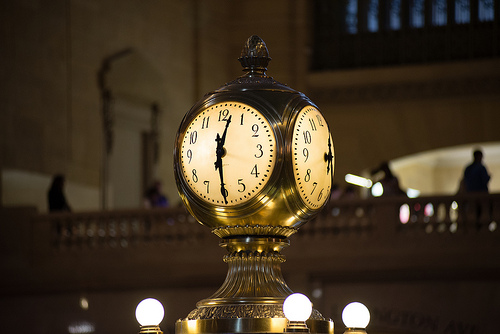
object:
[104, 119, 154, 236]
door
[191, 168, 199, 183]
numbers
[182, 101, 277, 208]
clock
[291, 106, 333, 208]
clock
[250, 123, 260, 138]
number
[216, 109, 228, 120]
number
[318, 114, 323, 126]
number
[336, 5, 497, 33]
windows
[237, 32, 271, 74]
brass piece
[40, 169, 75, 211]
person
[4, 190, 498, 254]
fence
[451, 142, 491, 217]
person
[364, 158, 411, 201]
person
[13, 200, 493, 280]
balcony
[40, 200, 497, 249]
barrier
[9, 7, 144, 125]
wall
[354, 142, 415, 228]
bulb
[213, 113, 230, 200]
hand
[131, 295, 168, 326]
lights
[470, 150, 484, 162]
head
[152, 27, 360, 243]
piece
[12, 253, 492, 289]
floor